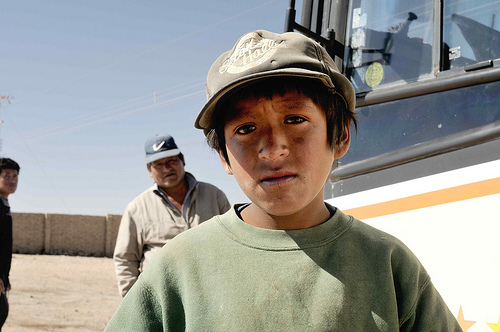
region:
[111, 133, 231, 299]
old man wearing nike hat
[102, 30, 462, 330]
young kid wearing dirty hat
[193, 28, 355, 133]
kid is wearing black hat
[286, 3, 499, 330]
large vehicle behind kid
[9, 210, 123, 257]
stone wall in background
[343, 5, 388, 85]
several stickers on vehicle in background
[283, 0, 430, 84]
side view mirror in reflection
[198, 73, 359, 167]
person has black uneven hair under hat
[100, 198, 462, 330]
person is wearing grey sweater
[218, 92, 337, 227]
closest person face is covered in dust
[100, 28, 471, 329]
young boy in green sweatshirt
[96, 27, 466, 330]
young boy wearing gray cap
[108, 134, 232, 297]
man wearing blue cap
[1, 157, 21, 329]
man in dark clothing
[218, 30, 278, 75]
embroidery on boy's cap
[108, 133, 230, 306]
man with open shirt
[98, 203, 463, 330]
green sweatshirt on young boy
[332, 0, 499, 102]
windshield on vehicle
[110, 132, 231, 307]
man squinting at boy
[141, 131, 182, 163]
dark blue cap worn by man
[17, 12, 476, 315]
these people look reluctant to take a picture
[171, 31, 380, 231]
this boy has an indicisive look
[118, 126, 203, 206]
this man is wondering why the boy is being photographed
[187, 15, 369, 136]
the boy is wearing a grey baseball cap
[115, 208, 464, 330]
the boy has on a green sweat shirt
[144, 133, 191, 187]
this man is wearing a black cap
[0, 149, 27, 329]
this young man is in the picture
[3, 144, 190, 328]
the people are standing in the desert area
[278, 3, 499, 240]
a bus is besides the boys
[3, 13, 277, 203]
the sky does not have any clouds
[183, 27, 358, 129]
gray hat on the young boy's head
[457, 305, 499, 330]
orange and yellow star design on a bus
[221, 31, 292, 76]
white design on a gray hat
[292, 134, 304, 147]
black mark on a boy's face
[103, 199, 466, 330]
green sweater on a young boy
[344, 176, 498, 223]
orange line going across the side of a bus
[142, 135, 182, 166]
blue Nike hat on a man's head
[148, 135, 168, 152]
white Nike logo on a hat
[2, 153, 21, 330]
a man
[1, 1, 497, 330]
two men and boy standing near a bus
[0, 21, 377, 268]
Mexican males looking at camera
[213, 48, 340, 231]
Young Mexican boy looking at camera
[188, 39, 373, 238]
Boy is not smiling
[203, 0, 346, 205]
Boy wearing a baseball cap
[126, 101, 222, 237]
Young Mexican male wearing a Nike hat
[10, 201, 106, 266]
Brick fence in the distance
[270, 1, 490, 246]
Boy standing near large bus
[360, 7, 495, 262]
Bus is white black and orange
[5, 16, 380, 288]
mexican males standing at bus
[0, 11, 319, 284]
It is daytime and sunny